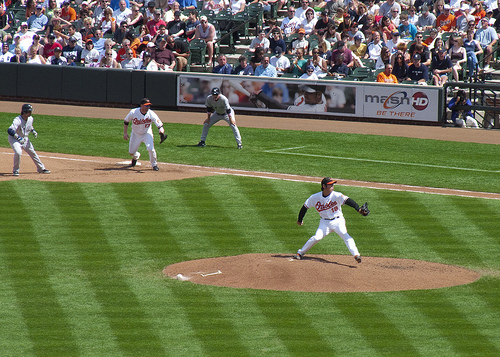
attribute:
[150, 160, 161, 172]
shoe — black 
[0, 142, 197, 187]
first base — first 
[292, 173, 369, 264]
baseball player — baseball 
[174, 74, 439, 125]
advertisement — masnHD television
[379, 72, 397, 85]
shirt — orange 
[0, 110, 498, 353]
grass — Maintained lawn 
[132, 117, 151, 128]
letters — red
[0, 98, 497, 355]
baseball field — baseball 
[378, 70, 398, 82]
orange shirt — orange 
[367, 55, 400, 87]
shirt — orange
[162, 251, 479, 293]
dirt — brown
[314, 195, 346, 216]
name — team 